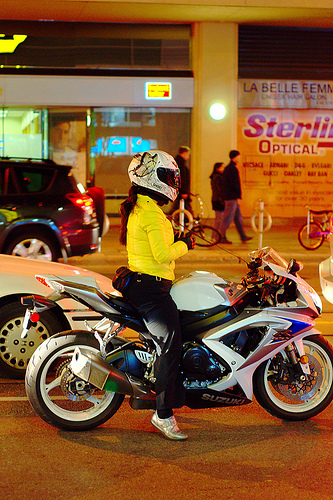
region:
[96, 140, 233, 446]
a girl riding a motorcycle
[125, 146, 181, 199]
an artsy helmet on a head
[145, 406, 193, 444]
a silver shoes touching the street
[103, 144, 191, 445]
a girl wearing a yellow jacket and black gloves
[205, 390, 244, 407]
a company name on motorcycle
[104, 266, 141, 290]
a leather black fanny pack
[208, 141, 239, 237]
a couple strolling along the sidewalk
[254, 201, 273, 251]
a white pole with a circle lock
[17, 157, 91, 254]
a dark blue suv driving down the street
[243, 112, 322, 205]
a large yellow and red adverstisement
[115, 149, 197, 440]
The woman on the motorcycle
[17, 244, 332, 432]
The motorcycle the woman is on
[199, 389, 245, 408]
The name suzuki on the motorcycle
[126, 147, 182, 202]
The white helmet on the woman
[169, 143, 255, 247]
The people walking on the sidewalk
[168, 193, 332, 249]
The two bicycles parked on the sidewalk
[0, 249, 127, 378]
The front end of the white car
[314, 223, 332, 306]
The back end of a white car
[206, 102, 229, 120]
The circular light on the building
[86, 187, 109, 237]
Tire on the back of the suv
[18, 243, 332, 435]
A very recent brand new motorcycle.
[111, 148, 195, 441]
A sexy young woman riding a bike.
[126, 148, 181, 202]
A beautiful helmet above a woman's head.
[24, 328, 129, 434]
One the wheels of the motorcycle.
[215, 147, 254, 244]
A young man taking a walk on the sidewalk.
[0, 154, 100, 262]
An SUV car riding on the other direction.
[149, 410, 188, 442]
A nice casual shoe on a young woman's foot.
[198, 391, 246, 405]
The brand of a Japanese company.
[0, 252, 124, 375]
A car riding in the same road as the motorcycle.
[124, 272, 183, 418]
A black pair of pants worn by a young woman.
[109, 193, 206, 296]
the woman is wearing a yellow jacket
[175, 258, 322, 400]
the motorcycle is white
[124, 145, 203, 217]
the woman is wearing a helmet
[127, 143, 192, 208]
the helmet is white with a design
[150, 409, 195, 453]
the woman's shoes are silver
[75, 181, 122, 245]
spare tire on the back of the car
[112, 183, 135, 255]
the woman has a ponytail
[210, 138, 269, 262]
people walking on the sidewalk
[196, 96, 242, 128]
the light is on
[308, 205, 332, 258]
the bike is parked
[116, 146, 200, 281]
The woman is wearing a yellow jacket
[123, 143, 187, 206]
The woman's helmet is white with a butterfly on it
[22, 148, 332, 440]
The woman is riding a white motorcycle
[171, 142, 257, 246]
Three people walking in the same direction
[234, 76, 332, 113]
A sign for a hair salon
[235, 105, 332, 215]
A sign for an eyeglass store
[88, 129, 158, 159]
A reflection of blue lights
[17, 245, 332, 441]
The motorcycle is sitting on pavement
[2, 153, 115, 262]
A grey SUV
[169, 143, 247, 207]
Three people wearing black jackets